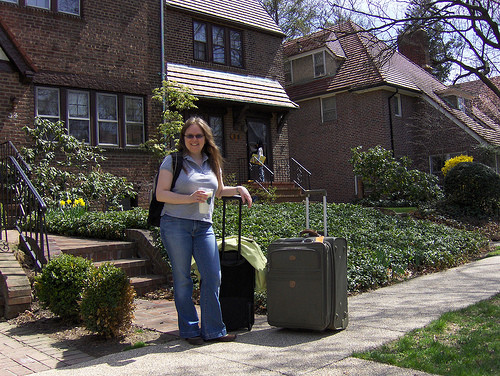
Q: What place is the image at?
A: It is at the sidewalk.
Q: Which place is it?
A: It is a sidewalk.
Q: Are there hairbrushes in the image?
A: No, there are no hairbrushes.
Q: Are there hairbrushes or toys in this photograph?
A: No, there are no hairbrushes or toys.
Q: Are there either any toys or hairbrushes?
A: No, there are no hairbrushes or toys.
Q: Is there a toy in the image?
A: No, there are no toys.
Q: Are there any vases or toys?
A: No, there are no toys or vases.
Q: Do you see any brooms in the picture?
A: No, there are no brooms.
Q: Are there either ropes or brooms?
A: No, there are no brooms or ropes.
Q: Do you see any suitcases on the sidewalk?
A: Yes, there is a suitcase on the sidewalk.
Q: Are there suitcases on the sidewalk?
A: Yes, there is a suitcase on the sidewalk.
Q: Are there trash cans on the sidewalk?
A: No, there is a suitcase on the sidewalk.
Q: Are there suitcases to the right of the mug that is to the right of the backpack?
A: Yes, there is a suitcase to the right of the mug.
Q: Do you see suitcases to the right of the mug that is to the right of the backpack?
A: Yes, there is a suitcase to the right of the mug.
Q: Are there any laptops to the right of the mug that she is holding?
A: No, there is a suitcase to the right of the mug.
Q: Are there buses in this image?
A: No, there are no buses.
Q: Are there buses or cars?
A: No, there are no buses or cars.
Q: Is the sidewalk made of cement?
A: Yes, the sidewalk is made of cement.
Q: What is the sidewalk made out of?
A: The sidewalk is made of concrete.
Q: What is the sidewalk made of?
A: The sidewalk is made of concrete.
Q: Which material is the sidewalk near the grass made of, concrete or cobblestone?
A: The sidewalk is made of concrete.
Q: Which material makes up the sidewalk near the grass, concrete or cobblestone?
A: The sidewalk is made of concrete.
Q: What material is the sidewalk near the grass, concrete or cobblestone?
A: The sidewalk is made of concrete.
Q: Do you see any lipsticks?
A: No, there are no lipsticks.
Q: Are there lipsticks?
A: No, there are no lipsticks.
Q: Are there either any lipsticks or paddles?
A: No, there are no lipsticks or paddles.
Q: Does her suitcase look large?
A: Yes, the suitcase is large.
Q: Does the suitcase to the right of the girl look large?
A: Yes, the suitcase is large.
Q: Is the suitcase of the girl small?
A: No, the suitcase is large.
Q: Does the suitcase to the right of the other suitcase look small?
A: No, the suitcase is large.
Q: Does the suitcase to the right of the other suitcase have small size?
A: No, the suitcase is large.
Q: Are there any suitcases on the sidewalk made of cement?
A: Yes, there is a suitcase on the sidewalk.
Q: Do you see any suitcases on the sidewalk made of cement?
A: Yes, there is a suitcase on the sidewalk.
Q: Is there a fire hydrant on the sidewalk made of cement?
A: No, there is a suitcase on the sidewalk.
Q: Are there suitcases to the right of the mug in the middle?
A: Yes, there is a suitcase to the right of the mug.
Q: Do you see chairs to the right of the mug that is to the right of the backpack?
A: No, there is a suitcase to the right of the mug.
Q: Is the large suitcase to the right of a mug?
A: Yes, the suitcase is to the right of a mug.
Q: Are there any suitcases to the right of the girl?
A: Yes, there is a suitcase to the right of the girl.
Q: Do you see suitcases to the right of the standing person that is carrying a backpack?
A: Yes, there is a suitcase to the right of the girl.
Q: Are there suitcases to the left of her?
A: No, the suitcase is to the right of the girl.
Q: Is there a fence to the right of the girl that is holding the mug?
A: No, there is a suitcase to the right of the girl.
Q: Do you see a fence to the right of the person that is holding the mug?
A: No, there is a suitcase to the right of the girl.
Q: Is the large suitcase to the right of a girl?
A: Yes, the suitcase is to the right of a girl.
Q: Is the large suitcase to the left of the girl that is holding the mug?
A: No, the suitcase is to the right of the girl.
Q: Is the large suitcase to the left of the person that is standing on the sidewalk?
A: No, the suitcase is to the right of the girl.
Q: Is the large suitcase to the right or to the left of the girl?
A: The suitcase is to the right of the girl.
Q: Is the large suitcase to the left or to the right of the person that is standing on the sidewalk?
A: The suitcase is to the right of the girl.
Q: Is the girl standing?
A: Yes, the girl is standing.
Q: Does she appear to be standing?
A: Yes, the girl is standing.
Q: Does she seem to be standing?
A: Yes, the girl is standing.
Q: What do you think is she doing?
A: The girl is standing.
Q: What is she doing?
A: The girl is standing.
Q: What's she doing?
A: The girl is standing.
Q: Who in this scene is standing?
A: The girl is standing.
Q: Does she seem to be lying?
A: No, the girl is standing.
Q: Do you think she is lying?
A: No, the girl is standing.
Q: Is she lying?
A: No, the girl is standing.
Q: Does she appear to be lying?
A: No, the girl is standing.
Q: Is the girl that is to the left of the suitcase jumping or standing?
A: The girl is standing.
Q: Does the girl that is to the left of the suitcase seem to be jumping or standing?
A: The girl is standing.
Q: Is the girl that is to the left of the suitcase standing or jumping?
A: The girl is standing.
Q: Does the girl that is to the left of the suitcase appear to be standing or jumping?
A: The girl is standing.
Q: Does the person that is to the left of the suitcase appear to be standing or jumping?
A: The girl is standing.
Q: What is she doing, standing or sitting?
A: The girl is standing.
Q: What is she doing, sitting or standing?
A: The girl is standing.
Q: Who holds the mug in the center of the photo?
A: The girl holds the mug.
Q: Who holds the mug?
A: The girl holds the mug.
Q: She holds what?
A: The girl holds the mug.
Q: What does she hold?
A: The girl holds the mug.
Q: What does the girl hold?
A: The girl holds the mug.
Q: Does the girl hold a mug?
A: Yes, the girl holds a mug.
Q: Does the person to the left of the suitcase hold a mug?
A: Yes, the girl holds a mug.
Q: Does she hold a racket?
A: No, the girl holds a mug.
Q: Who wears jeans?
A: The girl wears jeans.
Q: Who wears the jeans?
A: The girl wears jeans.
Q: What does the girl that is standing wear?
A: The girl wears jeans.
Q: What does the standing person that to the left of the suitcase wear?
A: The girl wears jeans.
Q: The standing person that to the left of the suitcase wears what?
A: The girl wears jeans.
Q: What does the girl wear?
A: The girl wears jeans.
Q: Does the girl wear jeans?
A: Yes, the girl wears jeans.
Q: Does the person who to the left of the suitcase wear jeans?
A: Yes, the girl wears jeans.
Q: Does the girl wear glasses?
A: No, the girl wears jeans.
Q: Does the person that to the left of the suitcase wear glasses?
A: No, the girl wears jeans.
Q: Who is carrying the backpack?
A: The girl is carrying the backpack.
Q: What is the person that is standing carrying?
A: The girl is carrying a backpack.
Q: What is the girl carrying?
A: The girl is carrying a backpack.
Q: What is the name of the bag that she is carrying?
A: The bag is a backpack.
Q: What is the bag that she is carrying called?
A: The bag is a backpack.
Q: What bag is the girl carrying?
A: The girl is carrying a backpack.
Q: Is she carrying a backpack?
A: Yes, the girl is carrying a backpack.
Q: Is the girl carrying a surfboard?
A: No, the girl is carrying a backpack.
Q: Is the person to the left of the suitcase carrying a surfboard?
A: No, the girl is carrying a backpack.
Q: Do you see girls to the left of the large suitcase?
A: Yes, there is a girl to the left of the suitcase.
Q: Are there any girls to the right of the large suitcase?
A: No, the girl is to the left of the suitcase.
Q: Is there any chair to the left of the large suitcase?
A: No, there is a girl to the left of the suitcase.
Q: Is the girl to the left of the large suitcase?
A: Yes, the girl is to the left of the suitcase.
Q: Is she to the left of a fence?
A: No, the girl is to the left of the suitcase.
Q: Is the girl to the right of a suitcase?
A: No, the girl is to the left of a suitcase.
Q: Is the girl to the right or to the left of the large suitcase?
A: The girl is to the left of the suitcase.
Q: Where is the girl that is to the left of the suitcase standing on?
A: The girl is standing on the sidewalk.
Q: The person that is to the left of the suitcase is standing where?
A: The girl is standing on the sidewalk.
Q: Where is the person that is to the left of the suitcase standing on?
A: The girl is standing on the sidewalk.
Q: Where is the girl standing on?
A: The girl is standing on the sidewalk.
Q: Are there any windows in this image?
A: Yes, there is a window.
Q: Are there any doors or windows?
A: Yes, there is a window.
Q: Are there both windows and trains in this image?
A: No, there is a window but no trains.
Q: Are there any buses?
A: No, there are no buses.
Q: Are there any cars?
A: No, there are no cars.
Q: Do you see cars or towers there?
A: No, there are no cars or towers.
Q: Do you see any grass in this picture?
A: Yes, there is grass.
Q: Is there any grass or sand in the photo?
A: Yes, there is grass.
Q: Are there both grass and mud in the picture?
A: No, there is grass but no mud.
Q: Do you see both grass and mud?
A: No, there is grass but no mud.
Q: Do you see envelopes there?
A: No, there are no envelopes.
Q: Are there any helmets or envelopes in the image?
A: No, there are no envelopes or helmets.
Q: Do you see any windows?
A: Yes, there is a window.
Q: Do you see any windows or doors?
A: Yes, there is a window.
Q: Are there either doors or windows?
A: Yes, there is a window.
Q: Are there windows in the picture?
A: Yes, there is a window.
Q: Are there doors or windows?
A: Yes, there is a window.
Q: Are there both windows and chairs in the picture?
A: No, there is a window but no chairs.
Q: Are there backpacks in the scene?
A: Yes, there is a backpack.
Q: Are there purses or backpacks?
A: Yes, there is a backpack.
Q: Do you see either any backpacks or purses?
A: Yes, there is a backpack.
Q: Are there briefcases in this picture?
A: No, there are no briefcases.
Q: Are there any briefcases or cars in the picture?
A: No, there are no briefcases or cars.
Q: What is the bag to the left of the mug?
A: The bag is a backpack.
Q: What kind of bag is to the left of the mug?
A: The bag is a backpack.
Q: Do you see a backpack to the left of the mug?
A: Yes, there is a backpack to the left of the mug.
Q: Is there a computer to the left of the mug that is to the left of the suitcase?
A: No, there is a backpack to the left of the mug.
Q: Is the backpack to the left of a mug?
A: Yes, the backpack is to the left of a mug.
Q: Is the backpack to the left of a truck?
A: No, the backpack is to the left of a mug.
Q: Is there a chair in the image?
A: No, there are no chairs.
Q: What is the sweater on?
A: The sweater is on the suitcase.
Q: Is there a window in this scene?
A: Yes, there is a window.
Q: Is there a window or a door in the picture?
A: Yes, there is a window.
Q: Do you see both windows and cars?
A: No, there is a window but no cars.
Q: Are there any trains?
A: No, there are no trains.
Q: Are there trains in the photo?
A: No, there are no trains.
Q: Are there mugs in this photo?
A: Yes, there is a mug.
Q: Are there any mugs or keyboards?
A: Yes, there is a mug.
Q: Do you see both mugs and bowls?
A: No, there is a mug but no bowls.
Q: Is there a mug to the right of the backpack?
A: Yes, there is a mug to the right of the backpack.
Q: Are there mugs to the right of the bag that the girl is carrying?
A: Yes, there is a mug to the right of the backpack.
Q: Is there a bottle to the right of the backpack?
A: No, there is a mug to the right of the backpack.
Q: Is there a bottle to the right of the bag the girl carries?
A: No, there is a mug to the right of the backpack.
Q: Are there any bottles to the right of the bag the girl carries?
A: No, there is a mug to the right of the backpack.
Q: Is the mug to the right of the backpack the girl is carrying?
A: Yes, the mug is to the right of the backpack.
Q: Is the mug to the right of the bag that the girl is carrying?
A: Yes, the mug is to the right of the backpack.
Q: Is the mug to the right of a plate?
A: No, the mug is to the right of the backpack.